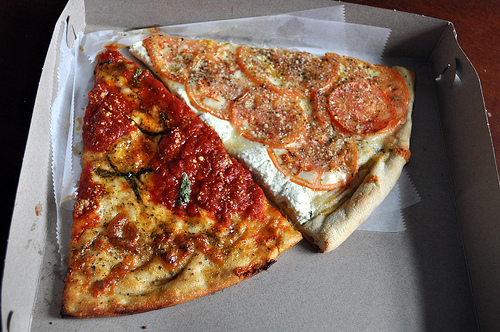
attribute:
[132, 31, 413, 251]
slice of pizza — pepperoni pizza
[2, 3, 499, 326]
box — made of cardboard, gray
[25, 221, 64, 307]
splat of grease — splattering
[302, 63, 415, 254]
crust of pizza — white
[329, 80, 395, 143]
tomato — thinly sliced, red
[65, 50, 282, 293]
cheese — melted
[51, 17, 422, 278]
parchment paper — made out of wax, white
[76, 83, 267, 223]
tomato sauce — red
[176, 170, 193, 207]
piece of herb — green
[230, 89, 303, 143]
pepperoni — round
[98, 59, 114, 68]
spot — black